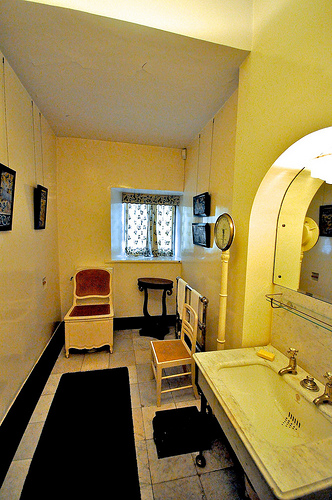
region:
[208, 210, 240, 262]
a wall mounted clock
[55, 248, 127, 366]
a large wooden chair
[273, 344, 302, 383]
a sink faucet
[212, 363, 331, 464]
a large sink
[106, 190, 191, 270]
a small window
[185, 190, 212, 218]
a framed picture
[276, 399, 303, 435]
a sink drain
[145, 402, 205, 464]
a small black stool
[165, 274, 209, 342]
a wooden towel rack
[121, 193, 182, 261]
curtains in a window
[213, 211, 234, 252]
round old fashioned clock with brown wood border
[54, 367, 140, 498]
large black oblong carpet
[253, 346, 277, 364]
small yellow bar of soap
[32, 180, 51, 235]
small black picture frame with white picture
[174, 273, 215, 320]
gold towel rack with white striped towel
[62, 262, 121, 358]
old fashioned tan chair with red velvet covering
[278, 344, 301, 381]
gold faucet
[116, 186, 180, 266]
blue and white patterned bathroom curtains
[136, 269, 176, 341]
small dark brown table with curly legs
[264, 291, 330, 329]
brown and green towel rack with backing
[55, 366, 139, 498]
a shag black runner rug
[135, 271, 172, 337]
a wooden end table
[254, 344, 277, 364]
a rectangular bar of soap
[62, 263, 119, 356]
a vintage looking chamberpot chair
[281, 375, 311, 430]
manually operated sink stopper drain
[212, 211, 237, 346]
antique weight scale dial on a post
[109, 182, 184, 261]
a window covered by drawn curtains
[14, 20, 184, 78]
cracked plaster on painted ceiling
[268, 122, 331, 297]
a lighted mirror above the sink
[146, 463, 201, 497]
tiles that appear were laid unevenly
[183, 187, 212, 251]
Twp pictures on a wall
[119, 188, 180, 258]
A window with curtains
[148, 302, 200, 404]
Chair with a brown seat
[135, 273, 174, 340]
A brown end table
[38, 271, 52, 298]
An empty toilet paper holder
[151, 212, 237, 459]
An old-fashioned bathroom scale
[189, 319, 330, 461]
A bathroom sink with faucets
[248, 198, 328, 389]
A curved mirror over a sink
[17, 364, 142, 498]
Black rug on a tile floor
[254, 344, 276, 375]
Piece of soap on a sink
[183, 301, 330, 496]
a bathroom sink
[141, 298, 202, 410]
a yellow chair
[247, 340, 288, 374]
a yellow bar of soap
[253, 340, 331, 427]
silver sink faucets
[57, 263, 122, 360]
a chair with red cushions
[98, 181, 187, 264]
a window with curtains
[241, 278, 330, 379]
a glass shelf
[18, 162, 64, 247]
a picture hanging on the wall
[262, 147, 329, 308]
a mirror above the sink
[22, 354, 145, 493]
a black rug on the floor